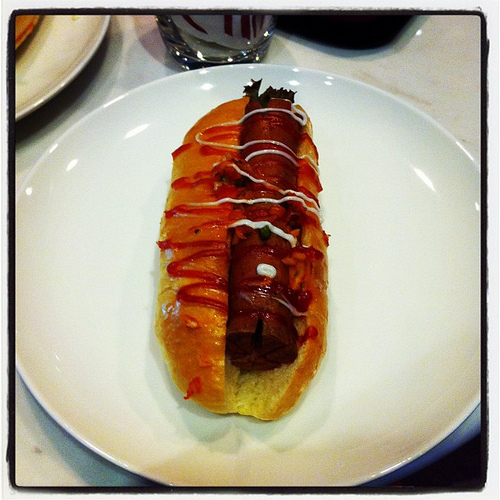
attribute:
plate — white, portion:
[20, 61, 485, 488]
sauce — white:
[165, 101, 326, 351]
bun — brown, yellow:
[151, 95, 331, 422]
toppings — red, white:
[179, 144, 347, 339]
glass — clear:
[154, 10, 279, 62]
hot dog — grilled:
[205, 93, 358, 410]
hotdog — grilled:
[227, 77, 304, 372]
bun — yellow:
[177, 328, 296, 405]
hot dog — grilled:
[226, 97, 299, 371]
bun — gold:
[160, 91, 248, 401]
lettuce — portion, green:
[234, 87, 307, 124]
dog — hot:
[243, 96, 287, 357]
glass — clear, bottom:
[166, 19, 264, 65]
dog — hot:
[222, 107, 294, 351]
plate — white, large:
[376, 180, 438, 330]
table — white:
[40, 438, 74, 468]